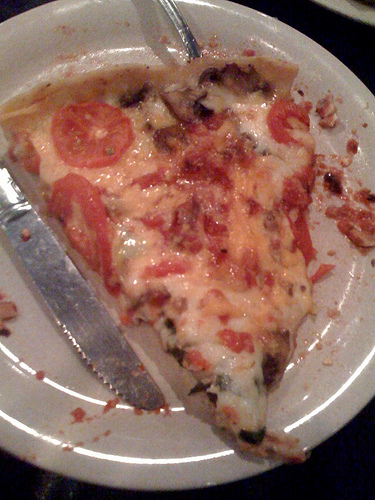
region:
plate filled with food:
[0, 41, 364, 439]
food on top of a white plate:
[26, 47, 344, 498]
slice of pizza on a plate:
[37, 58, 316, 433]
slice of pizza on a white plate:
[32, 52, 314, 464]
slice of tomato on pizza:
[49, 101, 148, 170]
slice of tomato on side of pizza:
[39, 187, 123, 275]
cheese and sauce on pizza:
[131, 144, 248, 293]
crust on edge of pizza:
[98, 56, 289, 89]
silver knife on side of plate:
[0, 204, 146, 429]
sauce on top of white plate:
[312, 155, 372, 293]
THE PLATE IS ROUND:
[1, 0, 371, 498]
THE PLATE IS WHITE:
[0, 0, 370, 496]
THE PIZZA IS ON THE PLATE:
[0, 38, 323, 462]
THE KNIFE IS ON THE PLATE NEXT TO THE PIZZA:
[0, 151, 169, 411]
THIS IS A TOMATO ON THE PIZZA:
[50, 94, 140, 167]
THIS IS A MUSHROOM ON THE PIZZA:
[159, 75, 223, 135]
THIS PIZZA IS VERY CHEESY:
[36, 91, 304, 459]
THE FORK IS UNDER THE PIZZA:
[155, 0, 207, 63]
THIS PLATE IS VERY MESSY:
[315, 82, 372, 279]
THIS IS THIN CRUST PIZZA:
[1, 50, 318, 188]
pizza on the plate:
[95, 78, 332, 326]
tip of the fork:
[116, 374, 176, 424]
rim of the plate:
[12, 405, 88, 477]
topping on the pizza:
[55, 77, 154, 171]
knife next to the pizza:
[24, 164, 198, 419]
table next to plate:
[320, 442, 366, 489]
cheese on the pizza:
[175, 241, 245, 310]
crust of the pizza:
[59, 59, 200, 101]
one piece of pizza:
[74, 113, 359, 426]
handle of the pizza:
[163, 8, 216, 49]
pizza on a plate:
[7, 45, 339, 462]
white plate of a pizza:
[1, 389, 207, 487]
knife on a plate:
[0, 183, 181, 427]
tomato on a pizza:
[51, 101, 138, 167]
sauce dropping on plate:
[66, 408, 87, 422]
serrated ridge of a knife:
[55, 317, 123, 396]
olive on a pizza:
[188, 95, 227, 130]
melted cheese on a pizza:
[239, 292, 295, 325]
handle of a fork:
[158, 4, 213, 60]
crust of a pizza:
[34, 72, 123, 95]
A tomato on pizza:
[49, 98, 137, 164]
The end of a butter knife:
[10, 211, 164, 408]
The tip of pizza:
[187, 349, 289, 452]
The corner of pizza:
[215, 46, 314, 125]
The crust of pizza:
[1, 63, 316, 129]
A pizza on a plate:
[4, 1, 366, 466]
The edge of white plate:
[14, 406, 304, 496]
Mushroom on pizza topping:
[152, 80, 223, 128]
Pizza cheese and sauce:
[110, 176, 287, 326]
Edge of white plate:
[305, 292, 371, 412]